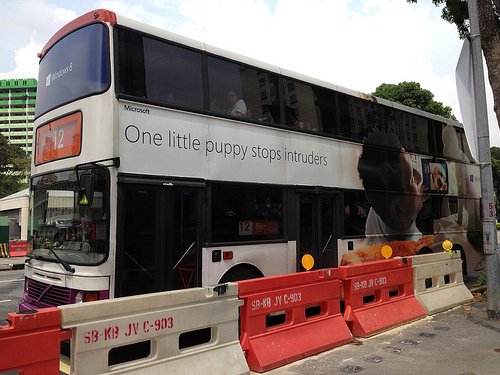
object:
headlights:
[72, 291, 82, 305]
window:
[212, 181, 290, 245]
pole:
[466, 1, 499, 320]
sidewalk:
[248, 296, 500, 374]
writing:
[121, 123, 328, 170]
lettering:
[80, 315, 175, 344]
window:
[280, 79, 335, 141]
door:
[295, 184, 341, 270]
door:
[115, 174, 199, 296]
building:
[0, 77, 38, 185]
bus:
[17, 8, 482, 355]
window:
[113, 26, 205, 117]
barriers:
[336, 257, 425, 339]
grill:
[24, 276, 71, 309]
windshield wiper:
[49, 246, 75, 275]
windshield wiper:
[23, 252, 58, 264]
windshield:
[27, 169, 109, 266]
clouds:
[0, 0, 498, 158]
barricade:
[230, 268, 353, 373]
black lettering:
[122, 123, 141, 144]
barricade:
[61, 280, 250, 374]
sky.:
[0, 0, 499, 151]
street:
[0, 249, 25, 326]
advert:
[117, 99, 482, 201]